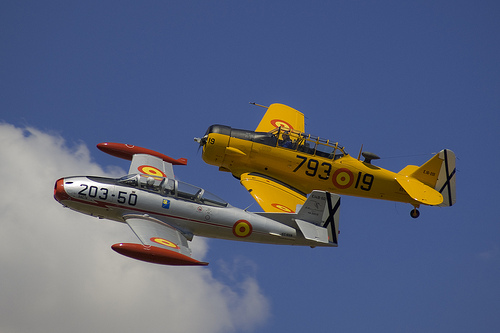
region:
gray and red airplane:
[46, 133, 350, 269]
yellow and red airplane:
[211, 97, 481, 257]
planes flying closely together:
[36, 79, 486, 286]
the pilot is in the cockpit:
[132, 168, 166, 205]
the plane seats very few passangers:
[245, 122, 352, 177]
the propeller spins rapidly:
[176, 112, 216, 164]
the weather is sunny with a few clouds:
[6, 36, 496, 331]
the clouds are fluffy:
[5, 112, 262, 331]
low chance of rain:
[8, 15, 492, 327]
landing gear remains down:
[408, 205, 422, 230]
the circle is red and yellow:
[159, 232, 181, 272]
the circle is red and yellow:
[164, 237, 169, 256]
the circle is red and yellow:
[165, 230, 173, 247]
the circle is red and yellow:
[162, 235, 172, 252]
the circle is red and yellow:
[154, 235, 174, 262]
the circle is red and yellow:
[161, 236, 167, 250]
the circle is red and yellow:
[167, 236, 168, 242]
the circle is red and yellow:
[162, 237, 180, 259]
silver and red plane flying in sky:
[49, 130, 355, 277]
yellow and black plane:
[192, 88, 474, 230]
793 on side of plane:
[290, 152, 337, 186]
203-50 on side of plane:
[77, 183, 147, 210]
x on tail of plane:
[437, 147, 472, 216]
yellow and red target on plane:
[229, 214, 259, 241]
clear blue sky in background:
[328, 20, 467, 107]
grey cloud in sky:
[2, 206, 64, 323]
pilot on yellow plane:
[268, 122, 348, 167]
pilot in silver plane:
[129, 169, 219, 209]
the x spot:
[324, 211, 334, 229]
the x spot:
[327, 208, 341, 240]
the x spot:
[324, 217, 335, 244]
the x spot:
[327, 212, 346, 251]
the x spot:
[327, 205, 339, 227]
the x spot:
[320, 212, 330, 230]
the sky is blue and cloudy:
[242, 289, 277, 321]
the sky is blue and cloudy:
[238, 272, 264, 299]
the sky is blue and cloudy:
[252, 278, 289, 307]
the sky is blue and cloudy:
[237, 298, 298, 332]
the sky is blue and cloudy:
[257, 274, 277, 291]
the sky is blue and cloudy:
[256, 290, 274, 305]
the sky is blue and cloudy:
[250, 309, 268, 314]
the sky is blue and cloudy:
[208, 265, 226, 276]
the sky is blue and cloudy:
[253, 308, 280, 330]